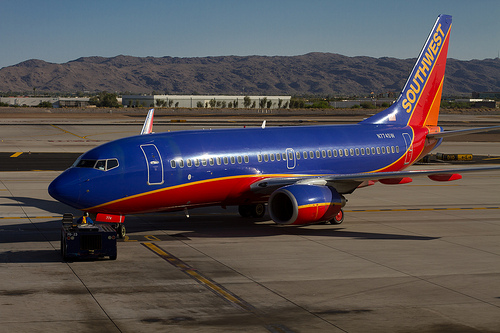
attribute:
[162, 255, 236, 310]
line — yellow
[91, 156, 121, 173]
window — first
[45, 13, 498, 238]
plane — blue and red, red and blue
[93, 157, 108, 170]
window — second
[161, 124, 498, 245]
stripe — orange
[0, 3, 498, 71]
sky — blue , clear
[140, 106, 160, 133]
wing — small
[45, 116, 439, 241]
paint — blue